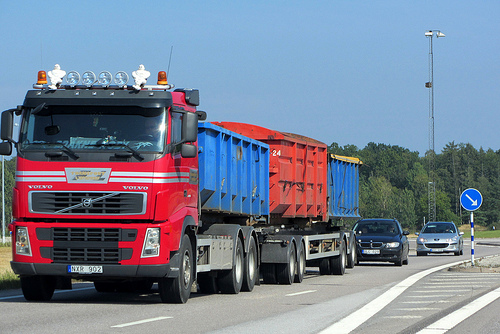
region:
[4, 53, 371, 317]
truck on a road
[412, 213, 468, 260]
car on a road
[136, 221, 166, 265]
front headlight on a vehicle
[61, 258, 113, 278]
front licence plate on a vehicle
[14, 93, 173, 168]
front windshield on a vehicle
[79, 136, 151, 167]
windshield wiper on a vehicle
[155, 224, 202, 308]
front wheel on a vehicle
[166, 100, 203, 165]
side rear view mirror on a vehicle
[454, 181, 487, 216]
blue and white sign on a pole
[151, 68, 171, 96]
orange light on the roof of a vehicle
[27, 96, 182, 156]
transfer trucks windshield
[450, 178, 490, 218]
round blue and white directional sign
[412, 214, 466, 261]
silver car driing down street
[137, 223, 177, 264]
head light on front of transfer truck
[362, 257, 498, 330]
white lines painted on asphalt road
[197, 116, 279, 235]
blue steel truck bed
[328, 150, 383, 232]
blue steel cargo bay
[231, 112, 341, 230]
red steel cargo transfer bin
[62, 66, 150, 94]
clear lights on top of red transfer truck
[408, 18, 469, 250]
metal tower in the distance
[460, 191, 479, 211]
an arrow pointing southeast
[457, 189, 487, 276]
a blue and white sign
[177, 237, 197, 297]
the front left tire of a truck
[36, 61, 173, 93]
the lights on top of a large truck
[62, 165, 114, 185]
an emblem on the front of a truck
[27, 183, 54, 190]
the word volvo on the front of a truck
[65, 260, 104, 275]
the license plate on the front of a truck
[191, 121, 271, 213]
the blue section between two red sections of a truck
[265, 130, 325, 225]
a red truck section between two blue sections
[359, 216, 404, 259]
a dark blue car behind a truck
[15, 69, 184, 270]
front of truck is red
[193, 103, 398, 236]
containers on truck are red & blue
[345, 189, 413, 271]
black car behind truck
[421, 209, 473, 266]
car is silver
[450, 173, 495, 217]
the sign is blue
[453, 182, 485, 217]
down arrow on sign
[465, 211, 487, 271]
the pole is striped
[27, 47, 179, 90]
lights on truck are orange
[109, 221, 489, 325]
lines on road are white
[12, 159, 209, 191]
truck has gray stripes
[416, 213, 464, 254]
silver car driving down the road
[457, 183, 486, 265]
blue and white sign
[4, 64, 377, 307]
long red and blue truck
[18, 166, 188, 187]
two silver stripes painted on the front of the truck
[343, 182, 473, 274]
two cars driving behind the truck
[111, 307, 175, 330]
white lane line painted on the ground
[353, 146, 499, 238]
forest green trees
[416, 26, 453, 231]
tall streetlight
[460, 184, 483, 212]
arrow pointing horizontally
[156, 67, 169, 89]
orange light on top of the truck cab